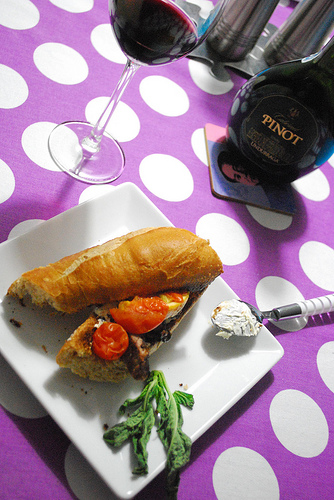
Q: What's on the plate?
A: Sandwich.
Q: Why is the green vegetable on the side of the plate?
A: Garnish.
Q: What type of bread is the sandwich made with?
A: French bread loaf.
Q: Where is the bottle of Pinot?
A: On table.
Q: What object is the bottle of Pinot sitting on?
A: Coaster.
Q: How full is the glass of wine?
A: Less than half full.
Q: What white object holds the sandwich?
A: Square plate.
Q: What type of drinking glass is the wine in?
A: Stemmed glass.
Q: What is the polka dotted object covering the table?
A: Tablecloth.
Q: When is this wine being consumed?
A: During mealtime.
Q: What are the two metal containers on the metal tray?
A: Salt and pepper shakers.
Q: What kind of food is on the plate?
A: A sandwich.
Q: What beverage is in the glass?
A: Red wine.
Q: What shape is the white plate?
A: Square.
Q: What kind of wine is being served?
A: Pinot.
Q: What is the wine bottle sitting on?
A: A coaster.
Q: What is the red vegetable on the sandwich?
A: Tomato.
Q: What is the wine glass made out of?
A: Glass.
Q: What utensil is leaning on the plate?
A: A spoon.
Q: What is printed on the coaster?
A: A person.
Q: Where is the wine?
A: In glass.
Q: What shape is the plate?
A: Square.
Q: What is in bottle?
A: Wine.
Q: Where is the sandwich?
A: On plate.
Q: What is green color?
A: Garnish.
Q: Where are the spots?
A: Tablecloth.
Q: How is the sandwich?
A: Toasted.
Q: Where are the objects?
A: In back.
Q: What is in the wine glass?
A: Wine.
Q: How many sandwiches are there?
A: One.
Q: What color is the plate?
A: White.